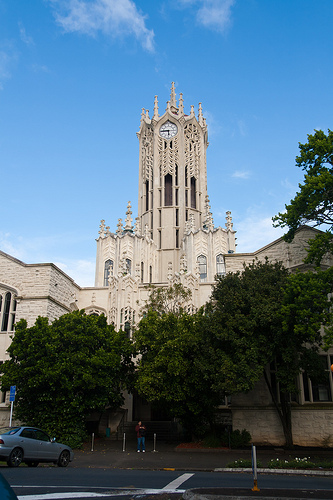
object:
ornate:
[135, 79, 211, 186]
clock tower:
[136, 81, 210, 282]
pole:
[153, 433, 157, 451]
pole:
[121, 432, 126, 451]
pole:
[89, 432, 94, 450]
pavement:
[46, 440, 332, 470]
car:
[0, 425, 73, 469]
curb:
[74, 464, 332, 478]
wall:
[225, 228, 332, 453]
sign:
[10, 384, 16, 404]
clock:
[158, 119, 178, 143]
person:
[133, 419, 147, 455]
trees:
[0, 306, 138, 451]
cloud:
[49, 0, 166, 61]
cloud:
[225, 164, 254, 184]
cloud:
[233, 178, 329, 256]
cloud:
[0, 220, 95, 290]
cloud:
[157, 0, 238, 39]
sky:
[0, 0, 332, 288]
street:
[1, 466, 332, 499]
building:
[0, 80, 332, 445]